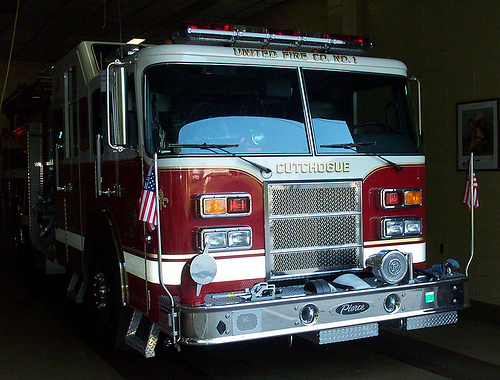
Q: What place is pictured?
A: It is a garage.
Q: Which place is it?
A: It is a garage.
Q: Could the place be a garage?
A: Yes, it is a garage.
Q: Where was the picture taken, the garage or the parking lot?
A: It was taken at the garage.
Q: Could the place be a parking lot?
A: No, it is a garage.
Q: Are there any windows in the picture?
A: Yes, there is a window.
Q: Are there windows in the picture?
A: Yes, there is a window.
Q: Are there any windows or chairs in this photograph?
A: Yes, there is a window.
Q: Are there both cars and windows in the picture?
A: No, there is a window but no cars.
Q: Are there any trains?
A: No, there are no trains.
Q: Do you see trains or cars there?
A: No, there are no trains or cars.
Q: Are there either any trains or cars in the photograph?
A: No, there are no trains or cars.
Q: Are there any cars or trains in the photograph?
A: No, there are no trains or cars.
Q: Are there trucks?
A: Yes, there is a truck.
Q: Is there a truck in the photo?
A: Yes, there is a truck.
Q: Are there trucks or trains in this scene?
A: Yes, there is a truck.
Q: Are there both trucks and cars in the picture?
A: No, there is a truck but no cars.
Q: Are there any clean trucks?
A: Yes, there is a clean truck.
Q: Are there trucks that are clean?
A: Yes, there is a truck that is clean.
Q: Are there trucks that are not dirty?
A: Yes, there is a clean truck.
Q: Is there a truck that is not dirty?
A: Yes, there is a clean truck.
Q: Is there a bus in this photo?
A: No, there are no buses.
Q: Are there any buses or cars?
A: No, there are no buses or cars.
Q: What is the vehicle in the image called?
A: The vehicle is a truck.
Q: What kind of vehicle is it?
A: The vehicle is a truck.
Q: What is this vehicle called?
A: This is a truck.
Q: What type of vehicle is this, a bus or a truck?
A: This is a truck.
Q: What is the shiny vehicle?
A: The vehicle is a truck.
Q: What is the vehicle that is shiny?
A: The vehicle is a truck.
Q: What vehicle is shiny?
A: The vehicle is a truck.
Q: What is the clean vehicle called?
A: The vehicle is a truck.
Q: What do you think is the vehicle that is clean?
A: The vehicle is a truck.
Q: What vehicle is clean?
A: The vehicle is a truck.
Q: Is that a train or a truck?
A: That is a truck.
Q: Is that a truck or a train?
A: That is a truck.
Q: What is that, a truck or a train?
A: That is a truck.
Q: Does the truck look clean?
A: Yes, the truck is clean.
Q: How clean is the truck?
A: The truck is clean.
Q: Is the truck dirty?
A: No, the truck is clean.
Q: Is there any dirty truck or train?
A: No, there is a truck but it is clean.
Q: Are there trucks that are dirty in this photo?
A: No, there is a truck but it is clean.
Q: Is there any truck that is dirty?
A: No, there is a truck but it is clean.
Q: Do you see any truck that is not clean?
A: No, there is a truck but it is clean.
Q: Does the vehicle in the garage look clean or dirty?
A: The truck is clean.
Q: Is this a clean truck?
A: Yes, this is a clean truck.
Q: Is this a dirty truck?
A: No, this is a clean truck.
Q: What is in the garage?
A: The truck is in the garage.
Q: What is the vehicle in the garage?
A: The vehicle is a truck.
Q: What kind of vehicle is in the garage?
A: The vehicle is a truck.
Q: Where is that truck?
A: The truck is in the garage.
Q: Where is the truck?
A: The truck is in the garage.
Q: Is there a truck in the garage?
A: Yes, there is a truck in the garage.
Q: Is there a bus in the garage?
A: No, there is a truck in the garage.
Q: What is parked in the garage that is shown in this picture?
A: The truck is parked in the garage.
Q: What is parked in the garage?
A: The truck is parked in the garage.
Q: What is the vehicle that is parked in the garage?
A: The vehicle is a truck.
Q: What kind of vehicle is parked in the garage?
A: The vehicle is a truck.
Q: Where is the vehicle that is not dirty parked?
A: The truck is parked in the garage.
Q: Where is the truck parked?
A: The truck is parked in the garage.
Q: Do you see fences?
A: No, there are no fences.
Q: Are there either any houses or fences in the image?
A: No, there are no fences or houses.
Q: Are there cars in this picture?
A: No, there are no cars.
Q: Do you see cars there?
A: No, there are no cars.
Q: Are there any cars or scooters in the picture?
A: No, there are no cars or scooters.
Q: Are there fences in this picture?
A: No, there are no fences.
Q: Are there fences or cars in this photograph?
A: No, there are no fences or cars.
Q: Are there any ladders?
A: No, there are no ladders.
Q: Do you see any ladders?
A: No, there are no ladders.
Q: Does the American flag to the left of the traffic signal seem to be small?
A: Yes, the American flag is small.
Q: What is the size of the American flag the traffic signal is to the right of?
A: The American flag is small.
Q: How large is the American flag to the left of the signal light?
A: The American flag is small.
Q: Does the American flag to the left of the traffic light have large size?
A: No, the American flag is small.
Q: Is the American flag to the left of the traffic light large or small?
A: The American flag is small.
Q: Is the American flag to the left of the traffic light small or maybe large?
A: The American flag is small.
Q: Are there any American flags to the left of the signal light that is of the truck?
A: Yes, there is an American flag to the left of the traffic light.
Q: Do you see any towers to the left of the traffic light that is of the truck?
A: No, there is an American flag to the left of the traffic light.